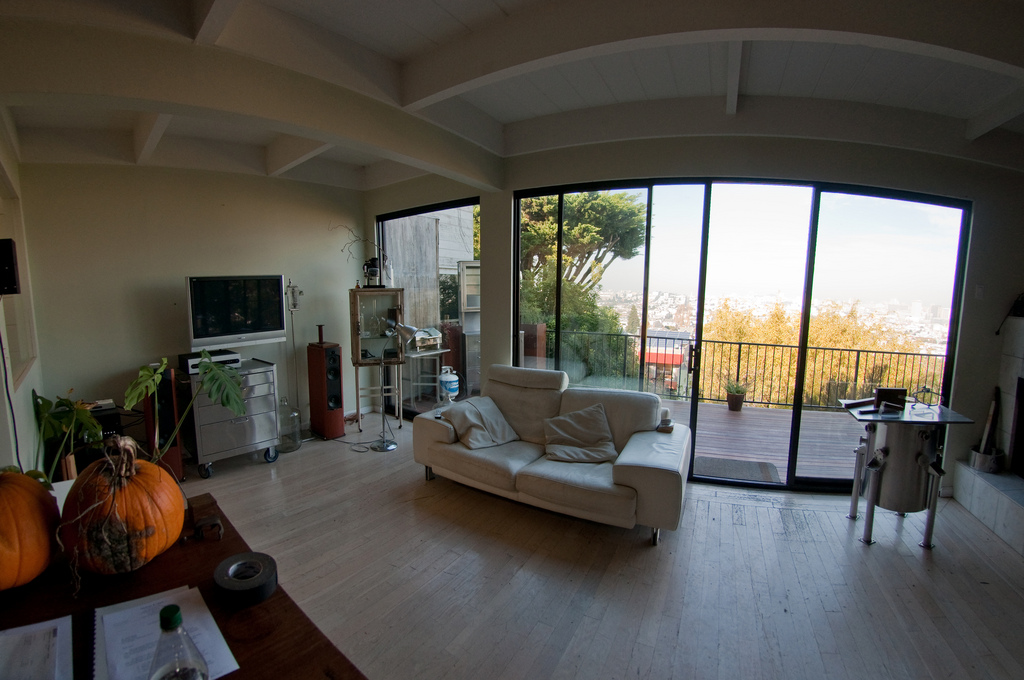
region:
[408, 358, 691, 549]
white leather couch on tiny legs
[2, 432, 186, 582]
two pumpkins sitting on a table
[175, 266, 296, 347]
tv mounted to the wall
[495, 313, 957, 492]
deck outside with metal railing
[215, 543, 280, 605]
roll of black tape on a table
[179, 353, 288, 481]
stainless steel cabinet on wheels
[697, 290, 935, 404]
tree tops visible over deck railing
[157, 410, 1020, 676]
blond wood floor with low sheen finish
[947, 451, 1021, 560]
stone tiles laid vertically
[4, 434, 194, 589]
The two pumpkins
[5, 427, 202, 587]
There are two pumpkins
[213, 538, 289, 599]
A roll of black tape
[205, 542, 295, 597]
The roll of black tape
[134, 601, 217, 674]
A bottle with a green cap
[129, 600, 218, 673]
A green cap bottle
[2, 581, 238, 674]
The papers on the counter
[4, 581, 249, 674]
A set of papers on the counter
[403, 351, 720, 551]
The white leather couch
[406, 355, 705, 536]
A white leather couch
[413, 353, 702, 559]
a white couch with 2 pillows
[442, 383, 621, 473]
throw pillows on a couch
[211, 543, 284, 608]
a duct tape roll on a table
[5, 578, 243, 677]
papers and envelopes on a table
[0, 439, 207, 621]
several pumpkins on a wooden table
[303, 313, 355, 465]
speaker sets with a wooden design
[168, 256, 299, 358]
wall mounted LCD TV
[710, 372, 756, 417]
pot with a plant on outdoor patio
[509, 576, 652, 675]
lightly colored wooden floor panel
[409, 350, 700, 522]
A tan couch in middle of room.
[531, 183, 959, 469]
Large window with a view.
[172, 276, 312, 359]
Tv on wall turned off.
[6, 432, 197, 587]
Two pumpkins sitting on table.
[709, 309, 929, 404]
Many trees with yellow leaves.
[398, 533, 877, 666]
Floor with brown wood panels.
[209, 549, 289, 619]
A roll of duct tape.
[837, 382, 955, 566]
Side table with assorted items.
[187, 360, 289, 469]
Set of dresser draws.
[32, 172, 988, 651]
A room with no people in it.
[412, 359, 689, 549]
white couch in the middle of living room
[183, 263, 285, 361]
big white tv in front of white wall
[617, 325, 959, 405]
black rails on the balcony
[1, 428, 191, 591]
orange pumpkins on top of brown wooden table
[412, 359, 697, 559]
Cream colored couch in living room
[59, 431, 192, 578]
Pumpking sitting on table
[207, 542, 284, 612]
Roll of black tape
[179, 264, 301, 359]
Flat screen television against wall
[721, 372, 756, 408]
Small plant sitting on deck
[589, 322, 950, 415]
Fence on deck outside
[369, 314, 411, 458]
Silver floor lamp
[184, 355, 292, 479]
TV stand holding TV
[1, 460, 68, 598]
Pumpkin sitting on table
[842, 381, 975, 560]
Table sitting on floor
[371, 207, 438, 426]
glass window in the building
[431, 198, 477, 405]
glass window in the building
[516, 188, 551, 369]
glass window in the building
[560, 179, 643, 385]
glass window in the building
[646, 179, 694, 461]
glass window in the building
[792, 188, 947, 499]
glass window in the building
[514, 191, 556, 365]
glass window in the building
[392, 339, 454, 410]
glass window in the building